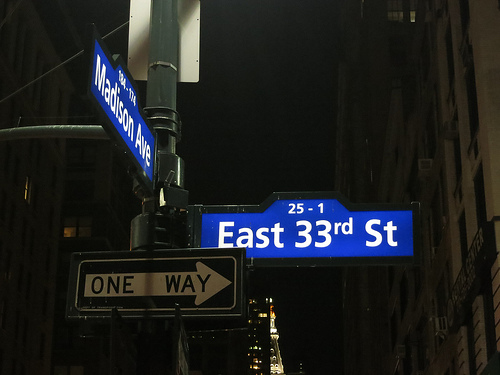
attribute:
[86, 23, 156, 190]
sign — white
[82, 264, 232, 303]
arrow — black, pointed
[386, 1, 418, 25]
lights — showing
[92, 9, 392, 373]
sky — black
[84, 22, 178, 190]
sign — blue